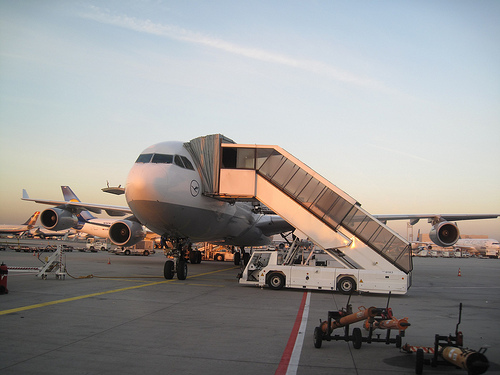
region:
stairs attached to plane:
[217, 139, 412, 290]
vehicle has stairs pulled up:
[217, 144, 415, 299]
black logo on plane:
[185, 180, 203, 198]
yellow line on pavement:
[1, 270, 233, 339]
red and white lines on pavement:
[271, 290, 321, 373]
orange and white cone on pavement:
[453, 266, 465, 279]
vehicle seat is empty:
[244, 253, 274, 285]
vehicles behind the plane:
[75, 237, 235, 262]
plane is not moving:
[23, 121, 499, 281]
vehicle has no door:
[243, 248, 277, 285]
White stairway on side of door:
[219, 140, 414, 297]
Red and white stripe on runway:
[274, 287, 312, 374]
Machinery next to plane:
[316, 289, 490, 373]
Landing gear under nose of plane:
[161, 238, 188, 280]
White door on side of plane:
[218, 142, 256, 202]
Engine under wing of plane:
[106, 214, 147, 247]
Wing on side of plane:
[371, 210, 499, 222]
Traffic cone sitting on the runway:
[456, 266, 462, 276]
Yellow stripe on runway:
[2, 264, 249, 317]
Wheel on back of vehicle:
[335, 274, 357, 295]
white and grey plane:
[21, 141, 499, 281]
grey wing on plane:
[21, 190, 133, 220]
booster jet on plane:
[107, 219, 144, 247]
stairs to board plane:
[221, 141, 413, 300]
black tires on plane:
[164, 259, 189, 279]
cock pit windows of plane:
[136, 152, 196, 172]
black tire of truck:
[268, 274, 284, 286]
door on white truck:
[248, 249, 272, 281]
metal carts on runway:
[313, 290, 410, 347]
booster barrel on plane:
[430, 222, 460, 247]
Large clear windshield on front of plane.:
[135, 149, 181, 171]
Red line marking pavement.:
[272, 327, 290, 361]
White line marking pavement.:
[296, 304, 318, 365]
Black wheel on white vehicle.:
[333, 273, 353, 287]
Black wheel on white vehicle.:
[259, 265, 294, 292]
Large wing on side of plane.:
[329, 194, 468, 229]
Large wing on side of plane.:
[46, 184, 138, 231]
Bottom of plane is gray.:
[140, 206, 199, 235]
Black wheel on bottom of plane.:
[161, 253, 193, 278]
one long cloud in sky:
[109, 0, 394, 100]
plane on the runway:
[100, 146, 232, 271]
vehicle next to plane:
[213, 228, 416, 305]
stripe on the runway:
[270, 299, 297, 374]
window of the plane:
[135, 144, 197, 178]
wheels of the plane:
[161, 258, 206, 288]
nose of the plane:
[127, 171, 157, 201]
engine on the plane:
[435, 217, 462, 254]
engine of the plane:
[98, 218, 137, 243]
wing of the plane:
[17, 191, 123, 218]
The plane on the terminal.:
[118, 140, 213, 276]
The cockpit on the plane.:
[135, 146, 185, 173]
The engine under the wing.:
[427, 222, 458, 247]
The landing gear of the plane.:
[152, 248, 207, 281]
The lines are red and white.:
[291, 285, 321, 360]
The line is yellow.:
[18, 278, 153, 310]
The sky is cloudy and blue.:
[36, 15, 446, 117]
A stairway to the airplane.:
[218, 146, 421, 296]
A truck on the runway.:
[73, 233, 113, 254]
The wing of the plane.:
[371, 205, 499, 232]